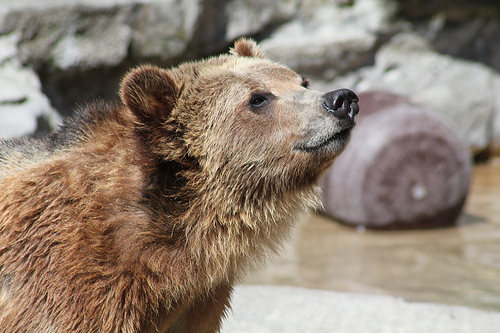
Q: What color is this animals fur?
A: Brown.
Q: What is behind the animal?
A: Rocks.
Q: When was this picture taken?
A: Daytime.